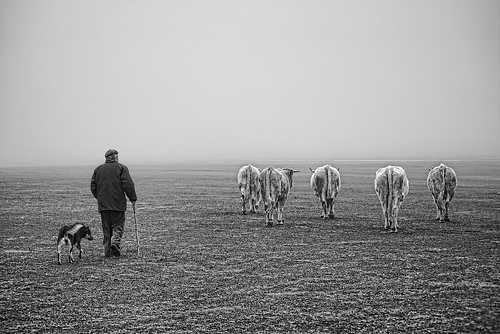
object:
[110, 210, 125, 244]
leg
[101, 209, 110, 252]
leg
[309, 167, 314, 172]
horn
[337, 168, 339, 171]
horn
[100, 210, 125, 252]
pants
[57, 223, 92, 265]
dog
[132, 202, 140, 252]
stick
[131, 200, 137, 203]
man's hand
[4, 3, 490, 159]
sky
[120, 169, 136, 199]
arm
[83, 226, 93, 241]
head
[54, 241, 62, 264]
leg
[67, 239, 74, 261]
leg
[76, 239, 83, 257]
leg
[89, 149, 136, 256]
man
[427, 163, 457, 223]
cattle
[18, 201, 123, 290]
dog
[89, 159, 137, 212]
jacket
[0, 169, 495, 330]
ground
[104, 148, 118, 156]
hat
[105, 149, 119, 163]
head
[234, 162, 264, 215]
cow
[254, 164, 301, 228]
cow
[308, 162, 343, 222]
cow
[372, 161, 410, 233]
cow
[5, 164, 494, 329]
field